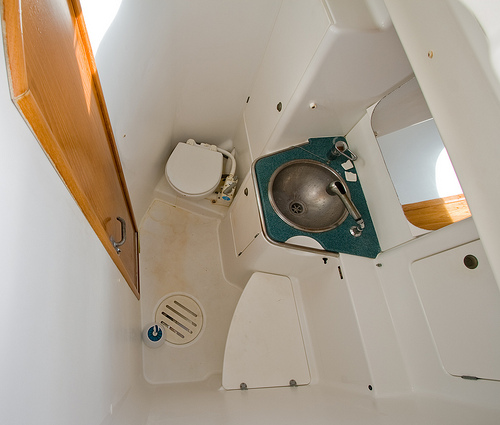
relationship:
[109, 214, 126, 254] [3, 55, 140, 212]
door knob on door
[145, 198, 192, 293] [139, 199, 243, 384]
stain on bathroom floor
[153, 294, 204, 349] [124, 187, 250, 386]
drain on floor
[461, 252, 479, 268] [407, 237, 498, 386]
hole on sink cover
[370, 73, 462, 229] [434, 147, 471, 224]
mirror has reflection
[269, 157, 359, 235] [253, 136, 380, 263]
bowl in sink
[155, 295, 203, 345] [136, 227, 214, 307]
drain in bathroom floor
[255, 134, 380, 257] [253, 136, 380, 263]
counter top has a chrome sink sink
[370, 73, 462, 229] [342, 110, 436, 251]
mirror on wall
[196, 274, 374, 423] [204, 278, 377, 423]
seat in corner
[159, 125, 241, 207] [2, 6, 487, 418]
toilet in bathroom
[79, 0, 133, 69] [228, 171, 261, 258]
light in access door